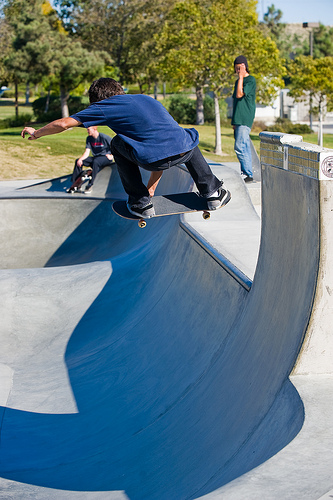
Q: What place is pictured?
A: It is a park.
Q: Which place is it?
A: It is a park.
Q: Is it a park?
A: Yes, it is a park.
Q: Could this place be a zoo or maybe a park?
A: It is a park.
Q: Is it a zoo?
A: No, it is a park.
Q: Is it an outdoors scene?
A: Yes, it is outdoors.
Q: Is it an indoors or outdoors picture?
A: It is outdoors.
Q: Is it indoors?
A: No, it is outdoors.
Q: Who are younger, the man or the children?
A: The children are younger than the man.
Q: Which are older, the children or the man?
A: The man are older than the children.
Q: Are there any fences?
A: No, there are no fences.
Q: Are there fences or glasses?
A: No, there are no fences or glasses.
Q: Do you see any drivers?
A: No, there are no drivers.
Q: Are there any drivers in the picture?
A: No, there are no drivers.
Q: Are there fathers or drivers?
A: No, there are no drivers or fathers.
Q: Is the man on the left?
A: Yes, the man is on the left of the image.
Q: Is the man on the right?
A: No, the man is on the left of the image.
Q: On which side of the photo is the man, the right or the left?
A: The man is on the left of the image.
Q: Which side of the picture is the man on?
A: The man is on the left of the image.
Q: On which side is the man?
A: The man is on the left of the image.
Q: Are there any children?
A: Yes, there are children.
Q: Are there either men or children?
A: Yes, there are children.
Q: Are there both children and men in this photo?
A: Yes, there are both children and a man.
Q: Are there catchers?
A: No, there are no catchers.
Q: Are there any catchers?
A: No, there are no catchers.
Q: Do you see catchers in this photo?
A: No, there are no catchers.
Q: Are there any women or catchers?
A: No, there are no catchers or women.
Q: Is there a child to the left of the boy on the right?
A: Yes, there are children to the left of the boy.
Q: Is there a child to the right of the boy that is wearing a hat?
A: No, the children are to the left of the boy.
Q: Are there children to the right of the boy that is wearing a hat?
A: No, the children are to the left of the boy.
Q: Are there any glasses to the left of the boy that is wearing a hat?
A: No, there are children to the left of the boy.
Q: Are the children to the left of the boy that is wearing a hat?
A: Yes, the children are to the left of the boy.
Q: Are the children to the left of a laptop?
A: No, the children are to the left of the boy.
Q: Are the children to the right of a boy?
A: No, the children are to the left of a boy.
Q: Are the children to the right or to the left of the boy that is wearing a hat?
A: The children are to the left of the boy.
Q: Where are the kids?
A: The kids are in the park.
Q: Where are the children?
A: The kids are in the park.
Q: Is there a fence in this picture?
A: No, there are no fences.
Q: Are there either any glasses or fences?
A: No, there are no fences or glasses.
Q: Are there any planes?
A: No, there are no planes.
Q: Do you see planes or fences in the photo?
A: No, there are no planes or fences.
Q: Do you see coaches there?
A: No, there are no coaches.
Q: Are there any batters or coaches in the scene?
A: No, there are no coaches or batters.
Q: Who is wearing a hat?
A: The boy is wearing a hat.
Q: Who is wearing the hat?
A: The boy is wearing a hat.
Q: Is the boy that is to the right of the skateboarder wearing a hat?
A: Yes, the boy is wearing a hat.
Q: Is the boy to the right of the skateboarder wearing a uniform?
A: No, the boy is wearing a hat.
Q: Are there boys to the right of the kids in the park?
A: Yes, there is a boy to the right of the children.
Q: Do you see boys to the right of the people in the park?
A: Yes, there is a boy to the right of the children.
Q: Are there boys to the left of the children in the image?
A: No, the boy is to the right of the children.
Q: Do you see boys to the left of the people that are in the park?
A: No, the boy is to the right of the children.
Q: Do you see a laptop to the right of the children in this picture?
A: No, there is a boy to the right of the children.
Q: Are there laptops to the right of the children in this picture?
A: No, there is a boy to the right of the children.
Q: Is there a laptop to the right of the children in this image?
A: No, there is a boy to the right of the children.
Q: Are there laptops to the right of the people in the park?
A: No, there is a boy to the right of the children.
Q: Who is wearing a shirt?
A: The boy is wearing a shirt.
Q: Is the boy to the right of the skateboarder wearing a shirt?
A: Yes, the boy is wearing a shirt.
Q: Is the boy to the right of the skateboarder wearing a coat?
A: No, the boy is wearing a shirt.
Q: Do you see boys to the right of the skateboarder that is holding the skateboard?
A: Yes, there is a boy to the right of the skateboarder.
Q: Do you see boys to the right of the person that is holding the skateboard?
A: Yes, there is a boy to the right of the skateboarder.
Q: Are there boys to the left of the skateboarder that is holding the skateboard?
A: No, the boy is to the right of the skateboarder.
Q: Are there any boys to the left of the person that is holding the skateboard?
A: No, the boy is to the right of the skateboarder.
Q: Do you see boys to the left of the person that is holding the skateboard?
A: No, the boy is to the right of the skateboarder.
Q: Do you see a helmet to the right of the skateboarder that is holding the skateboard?
A: No, there is a boy to the right of the skateboarder.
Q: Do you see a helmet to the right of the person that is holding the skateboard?
A: No, there is a boy to the right of the skateboarder.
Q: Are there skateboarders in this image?
A: Yes, there is a skateboarder.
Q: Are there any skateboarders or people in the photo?
A: Yes, there is a skateboarder.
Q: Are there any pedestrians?
A: No, there are no pedestrians.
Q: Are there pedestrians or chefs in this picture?
A: No, there are no pedestrians or chefs.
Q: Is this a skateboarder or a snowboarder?
A: This is a skateboarder.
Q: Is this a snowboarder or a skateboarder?
A: This is a skateboarder.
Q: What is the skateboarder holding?
A: The skateboarder is holding the skateboard.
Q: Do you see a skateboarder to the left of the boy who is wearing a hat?
A: Yes, there is a skateboarder to the left of the boy.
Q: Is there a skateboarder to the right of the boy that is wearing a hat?
A: No, the skateboarder is to the left of the boy.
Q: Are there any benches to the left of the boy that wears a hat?
A: No, there is a skateboarder to the left of the boy.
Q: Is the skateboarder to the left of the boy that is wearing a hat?
A: Yes, the skateboarder is to the left of the boy.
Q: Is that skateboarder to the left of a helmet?
A: No, the skateboarder is to the left of the boy.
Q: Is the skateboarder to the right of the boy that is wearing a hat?
A: No, the skateboarder is to the left of the boy.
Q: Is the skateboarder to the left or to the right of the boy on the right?
A: The skateboarder is to the left of the boy.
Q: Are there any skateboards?
A: Yes, there is a skateboard.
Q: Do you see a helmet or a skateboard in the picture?
A: Yes, there is a skateboard.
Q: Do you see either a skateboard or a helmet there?
A: Yes, there is a skateboard.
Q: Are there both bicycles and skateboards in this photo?
A: No, there is a skateboard but no bicycles.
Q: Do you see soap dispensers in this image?
A: No, there are no soap dispensers.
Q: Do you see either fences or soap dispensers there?
A: No, there are no soap dispensers or fences.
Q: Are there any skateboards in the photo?
A: Yes, there is a skateboard.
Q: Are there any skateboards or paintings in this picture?
A: Yes, there is a skateboard.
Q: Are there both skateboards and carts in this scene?
A: No, there is a skateboard but no carts.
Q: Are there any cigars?
A: No, there are no cigars.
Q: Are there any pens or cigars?
A: No, there are no cigars or pens.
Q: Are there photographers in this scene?
A: No, there are no photographers.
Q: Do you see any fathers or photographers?
A: No, there are no photographers or fathers.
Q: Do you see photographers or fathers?
A: No, there are no photographers or fathers.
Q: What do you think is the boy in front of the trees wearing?
A: The boy is wearing a shirt.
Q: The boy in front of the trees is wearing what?
A: The boy is wearing a shirt.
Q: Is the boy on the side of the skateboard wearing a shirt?
A: Yes, the boy is wearing a shirt.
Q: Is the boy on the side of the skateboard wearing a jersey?
A: No, the boy is wearing a shirt.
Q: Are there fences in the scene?
A: No, there are no fences.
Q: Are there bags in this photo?
A: No, there are no bags.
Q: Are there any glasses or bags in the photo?
A: No, there are no bags or glasses.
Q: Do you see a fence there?
A: No, there are no fences.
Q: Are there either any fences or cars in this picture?
A: No, there are no fences or cars.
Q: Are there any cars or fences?
A: No, there are no fences or cars.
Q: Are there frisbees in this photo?
A: No, there are no frisbees.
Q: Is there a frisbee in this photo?
A: No, there are no frisbees.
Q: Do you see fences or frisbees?
A: No, there are no frisbees or fences.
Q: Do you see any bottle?
A: No, there are no bottles.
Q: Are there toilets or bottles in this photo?
A: No, there are no bottles or toilets.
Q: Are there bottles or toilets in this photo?
A: No, there are no bottles or toilets.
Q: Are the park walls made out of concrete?
A: Yes, the walls are made of concrete.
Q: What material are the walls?
A: The walls are made of cement.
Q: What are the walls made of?
A: The walls are made of concrete.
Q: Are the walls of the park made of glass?
A: No, the walls are made of cement.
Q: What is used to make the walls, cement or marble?
A: The walls are made of cement.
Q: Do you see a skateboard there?
A: Yes, there is a skateboard.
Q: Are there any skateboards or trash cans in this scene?
A: Yes, there is a skateboard.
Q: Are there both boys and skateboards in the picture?
A: Yes, there are both a skateboard and a boy.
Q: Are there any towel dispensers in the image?
A: No, there are no towel dispensers.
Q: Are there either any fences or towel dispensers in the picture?
A: No, there are no towel dispensers or fences.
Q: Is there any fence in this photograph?
A: No, there are no fences.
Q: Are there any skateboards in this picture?
A: Yes, there is a skateboard.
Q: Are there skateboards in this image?
A: Yes, there is a skateboard.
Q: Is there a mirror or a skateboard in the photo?
A: Yes, there is a skateboard.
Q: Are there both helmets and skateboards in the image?
A: No, there is a skateboard but no helmets.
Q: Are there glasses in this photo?
A: No, there are no glasses.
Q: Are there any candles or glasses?
A: No, there are no glasses or candles.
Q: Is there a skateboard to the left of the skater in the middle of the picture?
A: Yes, there is a skateboard to the left of the skater.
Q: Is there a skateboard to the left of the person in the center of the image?
A: Yes, there is a skateboard to the left of the skater.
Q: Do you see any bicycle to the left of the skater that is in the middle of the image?
A: No, there is a skateboard to the left of the skater.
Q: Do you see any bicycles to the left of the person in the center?
A: No, there is a skateboard to the left of the skater.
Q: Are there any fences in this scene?
A: No, there are no fences.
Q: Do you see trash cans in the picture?
A: No, there are no trash cans.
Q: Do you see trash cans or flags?
A: No, there are no trash cans or flags.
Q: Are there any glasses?
A: No, there are no glasses.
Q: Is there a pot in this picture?
A: No, there are no pots.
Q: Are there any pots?
A: No, there are no pots.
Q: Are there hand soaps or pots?
A: No, there are no pots or hand soaps.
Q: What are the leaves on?
A: The leaves are on the tree.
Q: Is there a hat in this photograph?
A: Yes, there is a hat.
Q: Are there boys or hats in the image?
A: Yes, there is a hat.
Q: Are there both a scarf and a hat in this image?
A: No, there is a hat but no scarves.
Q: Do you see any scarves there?
A: No, there are no scarves.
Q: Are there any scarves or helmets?
A: No, there are no scarves or helmets.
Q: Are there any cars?
A: No, there are no cars.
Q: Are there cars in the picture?
A: No, there are no cars.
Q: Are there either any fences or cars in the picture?
A: No, there are no cars or fences.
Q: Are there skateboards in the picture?
A: Yes, there is a skateboard.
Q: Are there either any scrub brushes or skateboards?
A: Yes, there is a skateboard.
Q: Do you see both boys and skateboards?
A: Yes, there are both a skateboard and a boy.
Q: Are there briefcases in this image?
A: No, there are no briefcases.